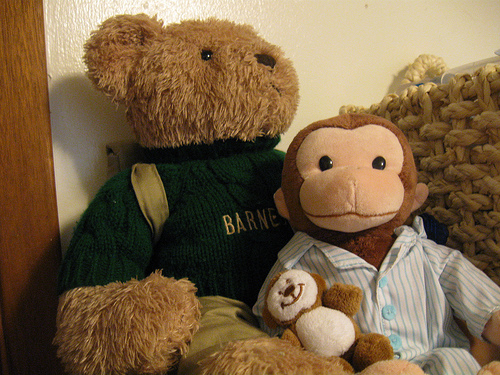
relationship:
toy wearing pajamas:
[294, 151, 403, 287] [397, 278, 439, 336]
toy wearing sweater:
[81, 12, 297, 375] [172, 169, 244, 220]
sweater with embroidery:
[172, 169, 244, 220] [241, 213, 274, 227]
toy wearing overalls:
[81, 12, 297, 375] [146, 186, 161, 206]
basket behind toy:
[446, 105, 498, 210] [294, 151, 403, 287]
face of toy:
[338, 139, 362, 215] [294, 151, 403, 287]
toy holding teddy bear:
[294, 151, 403, 287] [282, 288, 348, 349]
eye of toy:
[198, 43, 222, 63] [81, 12, 297, 375]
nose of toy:
[254, 54, 281, 69] [81, 12, 297, 375]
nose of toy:
[353, 189, 362, 194] [294, 151, 403, 287]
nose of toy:
[289, 289, 294, 294] [282, 288, 348, 349]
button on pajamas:
[381, 307, 397, 319] [397, 278, 439, 336]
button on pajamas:
[382, 281, 390, 288] [397, 278, 439, 336]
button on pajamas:
[394, 337, 401, 343] [397, 278, 439, 336]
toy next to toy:
[294, 151, 403, 287] [81, 12, 297, 375]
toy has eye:
[294, 151, 403, 287] [321, 159, 333, 168]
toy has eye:
[294, 151, 403, 287] [376, 156, 386, 168]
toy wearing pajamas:
[294, 151, 403, 287] [299, 242, 499, 342]